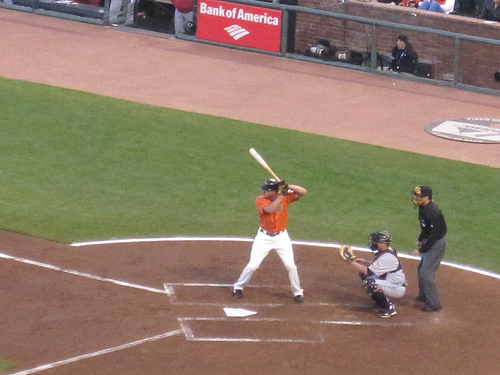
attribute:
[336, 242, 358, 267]
mit — brown, black, catchers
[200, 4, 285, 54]
banner — red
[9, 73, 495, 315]
grass — green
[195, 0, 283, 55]
banner — red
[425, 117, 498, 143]
sign — advertising 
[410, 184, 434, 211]
mask — black umpire , brown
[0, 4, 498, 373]
field — baseball field, base ball 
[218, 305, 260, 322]
home plate — white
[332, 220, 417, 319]
catcher — crouching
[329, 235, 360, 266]
gear — catcher's 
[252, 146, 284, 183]
bat — brown wooden baseball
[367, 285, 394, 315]
shin guards — black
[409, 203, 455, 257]
shirt — black